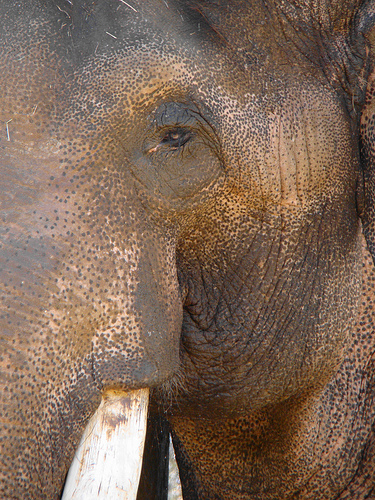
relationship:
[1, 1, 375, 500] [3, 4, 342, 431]
elephant has face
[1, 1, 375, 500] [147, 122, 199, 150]
elephant has eye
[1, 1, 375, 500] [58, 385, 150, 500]
elephant has tusk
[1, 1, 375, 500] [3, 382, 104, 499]
elephant has trunk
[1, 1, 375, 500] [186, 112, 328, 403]
elephant has wrinkles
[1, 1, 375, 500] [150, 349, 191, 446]
elephant has hair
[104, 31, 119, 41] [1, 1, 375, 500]
piece of straw on elephant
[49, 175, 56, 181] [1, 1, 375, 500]
spot on elephant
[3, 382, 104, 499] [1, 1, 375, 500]
trunk of elephant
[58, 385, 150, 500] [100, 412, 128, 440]
tusk has spot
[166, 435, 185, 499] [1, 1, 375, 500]
ground behind elephant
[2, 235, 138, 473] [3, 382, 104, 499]
discoloration on trunk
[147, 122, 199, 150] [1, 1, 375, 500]
eye of elephant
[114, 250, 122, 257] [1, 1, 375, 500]
spot on elephant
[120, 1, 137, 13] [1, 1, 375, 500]
piece of straw on elephant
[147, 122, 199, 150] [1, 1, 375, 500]
eye on elephant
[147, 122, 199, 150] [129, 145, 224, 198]
eye has bags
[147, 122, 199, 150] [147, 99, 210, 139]
eye has lid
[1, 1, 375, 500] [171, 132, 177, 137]
elephant has pupil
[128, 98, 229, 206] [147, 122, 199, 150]
wrinkles on eye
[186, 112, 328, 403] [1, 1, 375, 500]
wrinkles on elephant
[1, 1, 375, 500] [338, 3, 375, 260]
elephant has ear